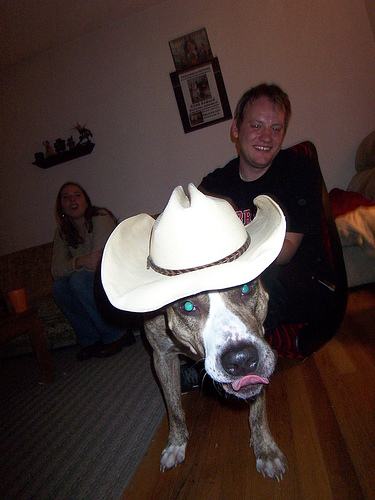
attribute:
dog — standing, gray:
[97, 179, 292, 488]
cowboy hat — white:
[96, 180, 290, 317]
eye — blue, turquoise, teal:
[174, 301, 201, 320]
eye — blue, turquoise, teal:
[237, 282, 252, 297]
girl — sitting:
[48, 176, 139, 367]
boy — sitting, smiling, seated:
[170, 76, 324, 400]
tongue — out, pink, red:
[228, 375, 274, 395]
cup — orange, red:
[4, 284, 33, 320]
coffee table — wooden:
[1, 304, 59, 382]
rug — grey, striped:
[2, 332, 173, 496]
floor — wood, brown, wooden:
[118, 277, 374, 499]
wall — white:
[1, 0, 375, 258]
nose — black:
[215, 337, 262, 380]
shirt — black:
[191, 146, 329, 291]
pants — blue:
[44, 267, 132, 351]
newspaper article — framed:
[170, 53, 234, 137]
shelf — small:
[26, 138, 104, 176]